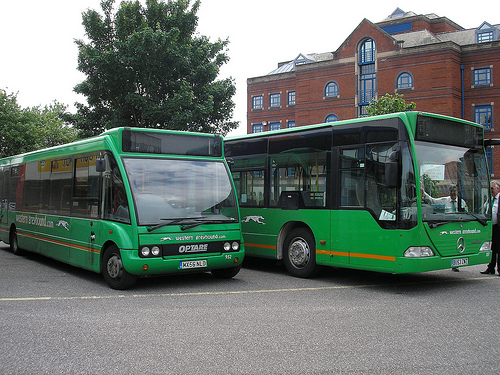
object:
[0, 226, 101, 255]
line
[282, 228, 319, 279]
wheel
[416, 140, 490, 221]
window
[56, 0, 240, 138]
tree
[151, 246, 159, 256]
lights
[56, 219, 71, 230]
symbol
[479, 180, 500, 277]
man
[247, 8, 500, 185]
buildings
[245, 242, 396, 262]
stripe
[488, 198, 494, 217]
tie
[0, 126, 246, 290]
bus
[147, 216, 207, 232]
windshield wipers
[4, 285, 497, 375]
pavement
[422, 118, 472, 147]
route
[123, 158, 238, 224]
windshield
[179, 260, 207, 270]
license tag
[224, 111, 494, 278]
right bus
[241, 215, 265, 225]
greyhound embleg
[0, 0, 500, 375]
photo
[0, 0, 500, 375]
daylight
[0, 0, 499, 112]
background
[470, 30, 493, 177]
in same direction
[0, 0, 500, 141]
sky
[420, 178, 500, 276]
two men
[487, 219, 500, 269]
black pants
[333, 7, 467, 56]
top of building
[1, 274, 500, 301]
line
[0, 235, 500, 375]
ground